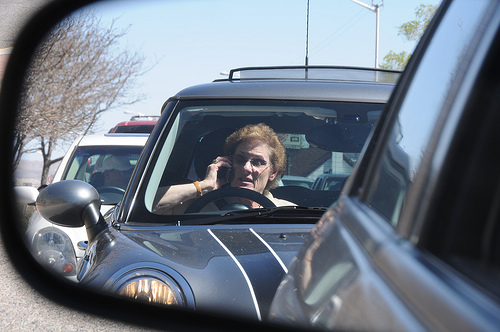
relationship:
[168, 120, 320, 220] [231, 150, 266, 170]
person has glasses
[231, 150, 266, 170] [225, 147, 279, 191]
glasses on face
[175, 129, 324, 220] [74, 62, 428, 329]
person driving car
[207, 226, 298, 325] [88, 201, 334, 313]
stripe on hood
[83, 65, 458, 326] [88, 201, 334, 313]
car has hood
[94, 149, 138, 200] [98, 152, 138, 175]
person wearing hat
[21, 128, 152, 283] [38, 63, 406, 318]
car behind car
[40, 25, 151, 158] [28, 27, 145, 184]
branches on tree